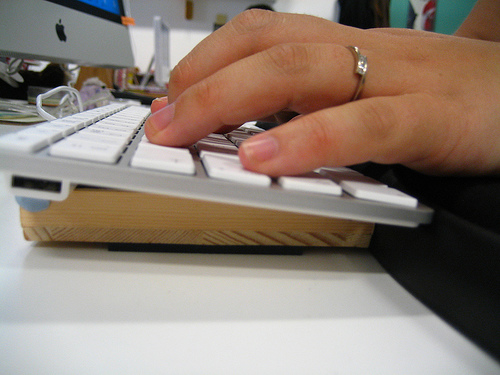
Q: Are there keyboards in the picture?
A: Yes, there is a keyboard.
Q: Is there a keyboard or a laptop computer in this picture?
A: Yes, there is a keyboard.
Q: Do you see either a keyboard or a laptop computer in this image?
A: Yes, there is a keyboard.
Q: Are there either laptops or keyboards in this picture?
A: Yes, there is a keyboard.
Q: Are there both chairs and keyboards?
A: No, there is a keyboard but no chairs.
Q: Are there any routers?
A: No, there are no routers.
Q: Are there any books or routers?
A: No, there are no routers or books.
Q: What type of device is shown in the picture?
A: The device is a keyboard.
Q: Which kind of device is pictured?
A: The device is a keyboard.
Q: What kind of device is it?
A: The device is a keyboard.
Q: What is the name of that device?
A: This is a keyboard.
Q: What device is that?
A: This is a keyboard.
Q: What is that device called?
A: This is a keyboard.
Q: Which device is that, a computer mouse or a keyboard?
A: This is a keyboard.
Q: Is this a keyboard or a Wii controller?
A: This is a keyboard.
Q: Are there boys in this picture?
A: No, there are no boys.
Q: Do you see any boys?
A: No, there are no boys.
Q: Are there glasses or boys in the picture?
A: No, there are no boys or glasses.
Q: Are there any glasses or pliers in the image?
A: No, there are no glasses or pliers.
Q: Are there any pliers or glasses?
A: No, there are no glasses or pliers.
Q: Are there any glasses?
A: No, there are no glasses.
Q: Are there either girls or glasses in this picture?
A: No, there are no glasses or girls.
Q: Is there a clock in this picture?
A: No, there are no clocks.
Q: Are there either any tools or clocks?
A: No, there are no clocks or tools.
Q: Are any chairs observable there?
A: No, there are no chairs.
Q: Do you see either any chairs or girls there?
A: No, there are no chairs or girls.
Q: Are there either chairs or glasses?
A: No, there are no glasses or chairs.